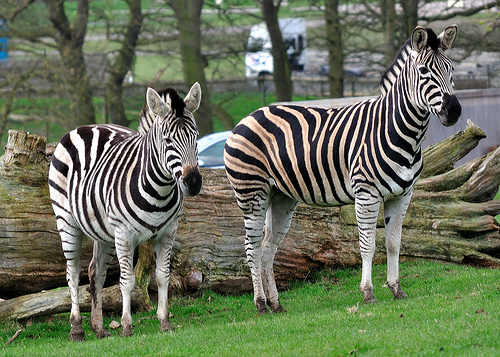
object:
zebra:
[39, 80, 205, 342]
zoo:
[0, 0, 500, 356]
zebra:
[221, 23, 463, 314]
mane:
[376, 20, 440, 99]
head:
[369, 20, 479, 144]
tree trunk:
[0, 119, 500, 336]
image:
[18, 23, 458, 331]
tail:
[87, 244, 100, 311]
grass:
[0, 0, 499, 356]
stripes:
[76, 125, 95, 173]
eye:
[162, 135, 173, 145]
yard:
[0, 263, 498, 357]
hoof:
[68, 325, 87, 340]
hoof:
[88, 326, 108, 336]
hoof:
[118, 325, 133, 337]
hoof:
[154, 318, 176, 332]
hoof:
[251, 294, 270, 313]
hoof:
[265, 299, 287, 311]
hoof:
[358, 284, 378, 302]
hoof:
[394, 292, 409, 301]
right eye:
[416, 63, 431, 76]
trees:
[0, 0, 500, 110]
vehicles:
[240, 15, 310, 83]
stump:
[1, 125, 48, 164]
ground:
[5, 245, 499, 353]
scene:
[0, 1, 495, 354]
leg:
[258, 190, 295, 308]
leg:
[86, 236, 111, 341]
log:
[0, 111, 499, 303]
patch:
[0, 255, 499, 355]